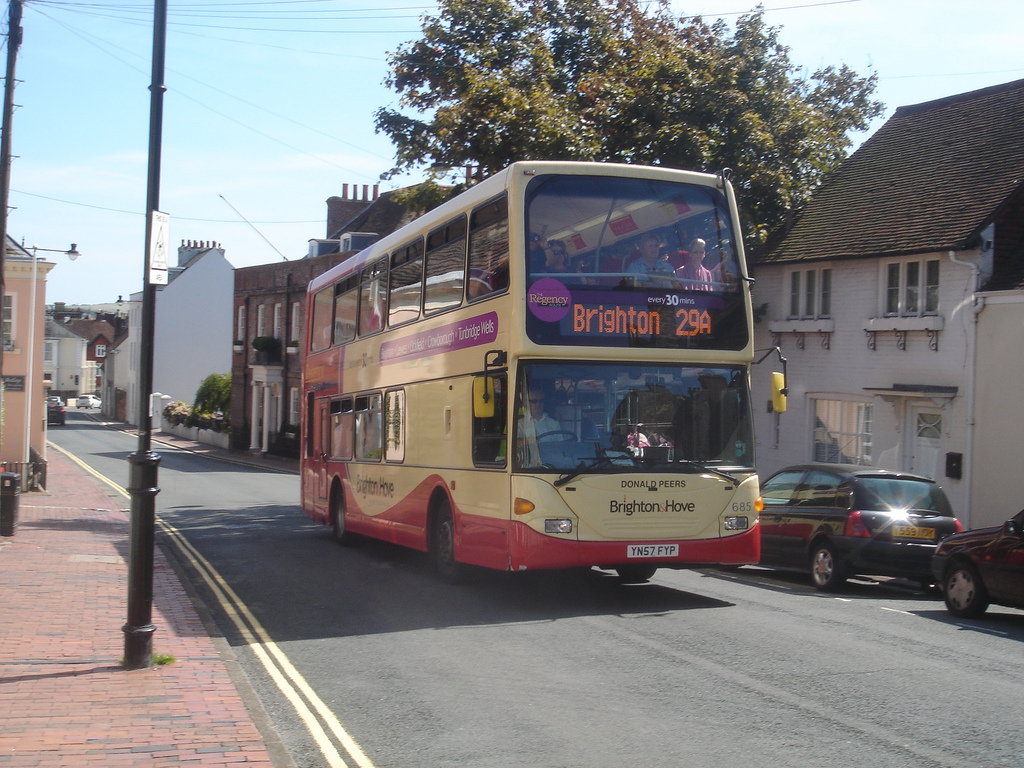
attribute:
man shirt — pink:
[674, 259, 717, 297]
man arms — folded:
[621, 269, 704, 290]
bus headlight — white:
[525, 507, 582, 542]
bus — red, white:
[276, 150, 776, 580]